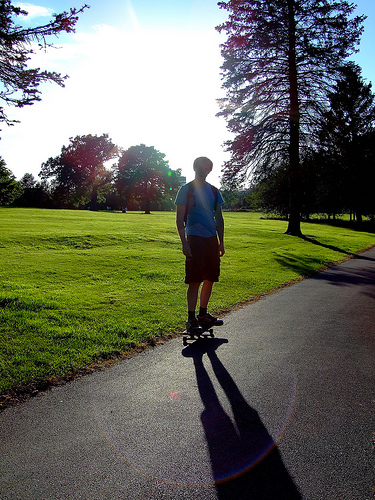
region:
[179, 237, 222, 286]
man wearing black shorts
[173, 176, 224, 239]
man wearing blue shirt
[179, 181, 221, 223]
man wearing backpack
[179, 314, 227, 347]
man standing on skateboard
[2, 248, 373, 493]
black asphalt path in park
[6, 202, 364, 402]
lush green grass in park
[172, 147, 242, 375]
This is a man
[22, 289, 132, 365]
Section of the field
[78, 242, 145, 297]
Section of the field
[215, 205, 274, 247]
Section of the field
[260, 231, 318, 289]
Section of the field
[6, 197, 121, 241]
Section of the field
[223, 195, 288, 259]
Section of the field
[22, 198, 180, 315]
Section of the field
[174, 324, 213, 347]
man riding on a skateboard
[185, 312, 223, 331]
man wearing white, black and red shoes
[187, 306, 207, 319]
man wearing long, black socks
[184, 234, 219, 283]
man wearing dark shorts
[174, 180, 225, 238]
man wearing a blue shirt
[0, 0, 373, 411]
man skateboarding next to park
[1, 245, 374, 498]
man skateboarding on the road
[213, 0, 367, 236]
large tree in the park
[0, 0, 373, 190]
sky is blue and sunny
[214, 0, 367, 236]
large tree beside sidewalk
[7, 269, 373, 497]
The road is paved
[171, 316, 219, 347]
The boy is riding a skateboard.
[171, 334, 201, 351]
The front wheel of the skateboard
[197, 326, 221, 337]
The back wheel of the skateboard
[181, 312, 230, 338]
The boy has on a pair of sneakers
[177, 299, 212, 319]
The boy has on a pair of low socks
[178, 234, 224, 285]
The boy has on brown shorts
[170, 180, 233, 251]
the boy has on a light blue shirt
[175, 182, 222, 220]
The straps from the backpack are displayed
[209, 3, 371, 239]
The very tall tree behind the boy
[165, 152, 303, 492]
shadow in front of skateboarder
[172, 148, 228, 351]
skateboarder on edge of paved path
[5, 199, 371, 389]
bright yellowish-green grass behind skateboarder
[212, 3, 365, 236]
tall tree with leaves and bare branches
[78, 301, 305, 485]
rainbow of light around skateboard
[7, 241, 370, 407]
brown organic matter along grass edge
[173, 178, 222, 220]
dark straps around the shoulders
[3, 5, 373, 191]
blue sky emitting bright light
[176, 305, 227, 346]
foot hanging over edge of skateboard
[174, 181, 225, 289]
skateboarder in blue t-shirt and dark shorts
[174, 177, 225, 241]
blue shirt with straps of a backpack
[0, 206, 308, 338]
area of green velvety grass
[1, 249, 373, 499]
a black topped road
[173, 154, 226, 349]
young man on a skateboard